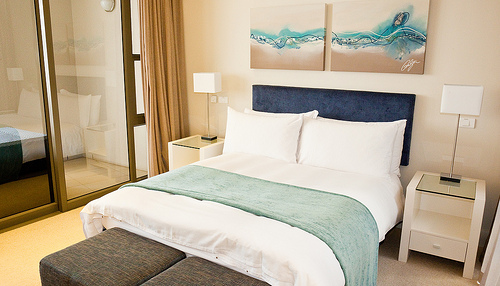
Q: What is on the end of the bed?
A: Stand.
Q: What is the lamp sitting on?
A: Nightstand.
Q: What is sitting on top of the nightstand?
A: Lamp.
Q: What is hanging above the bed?
A: Paintings.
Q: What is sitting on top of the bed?
A: Comforter.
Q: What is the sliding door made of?
A: Bronze.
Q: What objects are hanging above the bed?
A: Paintings.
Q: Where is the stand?
A: Beside bed.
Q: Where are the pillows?
A: On bed.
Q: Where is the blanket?
A: On bed.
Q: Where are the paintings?
A: On wall.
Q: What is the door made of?
A: Glass.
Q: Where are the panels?
A: On windows.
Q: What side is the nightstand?
A: Right.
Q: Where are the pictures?
A: Above bed.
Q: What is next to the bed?
A: The night stand.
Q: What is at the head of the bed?
A: Head board.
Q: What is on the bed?
A: The pillows.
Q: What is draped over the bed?
A: The blanket.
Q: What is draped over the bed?
A: Blanket.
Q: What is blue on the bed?
A: Head board.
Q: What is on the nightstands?
A: Lamps.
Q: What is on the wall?
A: Paintings.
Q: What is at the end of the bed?
A: A bench.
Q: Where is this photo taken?
A: A bedroom.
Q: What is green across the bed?
A: A throw.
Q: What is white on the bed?
A: Pillows and covers.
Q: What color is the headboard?
A: Navy.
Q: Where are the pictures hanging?
A: Above headboard.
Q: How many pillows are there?
A: Four.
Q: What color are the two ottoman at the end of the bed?
A: Brown.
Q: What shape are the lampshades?
A: Square.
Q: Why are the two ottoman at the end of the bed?
A: For sitting.